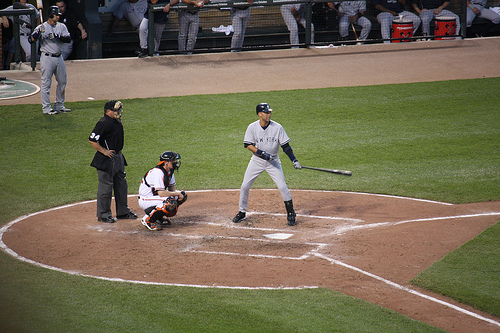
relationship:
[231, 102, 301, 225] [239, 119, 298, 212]
baseball player wearing a dress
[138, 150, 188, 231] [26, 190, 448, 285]
catcher crouching in dirt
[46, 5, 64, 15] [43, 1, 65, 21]
helmet on mans head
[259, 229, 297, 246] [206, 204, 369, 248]
home plate on batter's box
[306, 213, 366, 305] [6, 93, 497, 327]
lines on field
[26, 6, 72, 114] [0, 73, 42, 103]
man next deck circle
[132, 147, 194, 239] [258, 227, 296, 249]
catcher behind home base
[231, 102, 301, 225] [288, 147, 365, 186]
baseball player holds bat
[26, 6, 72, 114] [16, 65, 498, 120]
man on field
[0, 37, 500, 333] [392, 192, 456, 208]
floor with color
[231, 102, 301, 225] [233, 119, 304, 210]
baseball player wearing dress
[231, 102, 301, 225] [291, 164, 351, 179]
baseball player holding bat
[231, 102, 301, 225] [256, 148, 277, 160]
baseball player wearing gloves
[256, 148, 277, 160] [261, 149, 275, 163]
gloves on hand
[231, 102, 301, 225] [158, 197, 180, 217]
baseball player wearing pad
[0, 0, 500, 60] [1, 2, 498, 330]
people in stadium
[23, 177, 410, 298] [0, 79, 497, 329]
dirt with grass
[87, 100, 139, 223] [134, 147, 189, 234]
man stands behind catcher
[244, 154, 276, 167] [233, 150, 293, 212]
crease in pants